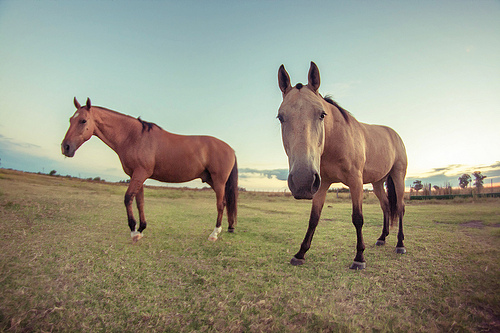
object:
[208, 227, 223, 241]
hoof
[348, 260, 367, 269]
hoof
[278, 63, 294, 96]
ear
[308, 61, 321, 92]
ear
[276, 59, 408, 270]
horse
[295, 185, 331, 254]
legs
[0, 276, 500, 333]
ground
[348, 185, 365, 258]
front legs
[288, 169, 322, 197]
nose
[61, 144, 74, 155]
nose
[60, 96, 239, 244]
horse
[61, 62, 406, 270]
horses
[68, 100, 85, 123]
blaze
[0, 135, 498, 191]
clouds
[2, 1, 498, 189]
sky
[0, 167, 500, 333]
grass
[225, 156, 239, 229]
tail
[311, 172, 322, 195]
horse nostril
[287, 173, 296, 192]
horse nostril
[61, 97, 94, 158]
head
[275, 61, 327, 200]
head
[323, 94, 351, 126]
mane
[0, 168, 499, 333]
field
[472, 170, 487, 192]
tree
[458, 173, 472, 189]
tree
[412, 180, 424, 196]
tree